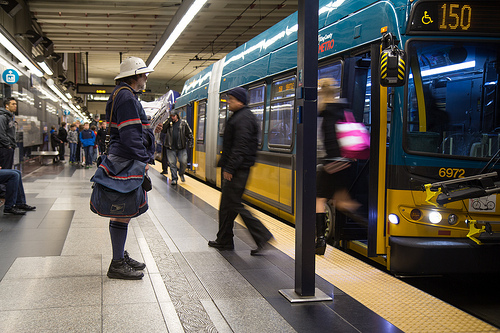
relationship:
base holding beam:
[280, 285, 332, 305] [294, 0, 317, 296]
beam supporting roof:
[289, 0, 320, 303] [204, 50, 286, 75]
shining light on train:
[428, 210, 442, 223] [166, 0, 498, 303]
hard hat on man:
[113, 55, 153, 79] [72, 81, 186, 202]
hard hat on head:
[113, 55, 153, 79] [95, 40, 167, 94]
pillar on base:
[297, 0, 315, 300] [276, 287, 331, 303]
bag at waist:
[85, 152, 156, 221] [94, 145, 162, 181]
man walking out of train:
[207, 88, 281, 256] [166, 0, 498, 303]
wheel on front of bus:
[311, 194, 343, 253] [159, 16, 491, 273]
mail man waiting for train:
[90, 55, 155, 280] [166, 0, 498, 303]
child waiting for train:
[67, 123, 78, 166] [166, 0, 498, 303]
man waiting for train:
[1, 98, 20, 170] [166, 0, 498, 303]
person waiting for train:
[0, 167, 35, 217] [166, 0, 498, 303]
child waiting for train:
[78, 122, 95, 166] [166, 0, 498, 303]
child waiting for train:
[67, 123, 78, 166] [172, 23, 498, 287]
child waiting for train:
[78, 122, 95, 166] [172, 23, 498, 287]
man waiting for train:
[1, 97, 41, 219] [125, 22, 497, 289]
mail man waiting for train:
[88, 55, 155, 280] [154, 0, 499, 279]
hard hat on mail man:
[113, 55, 153, 79] [90, 55, 155, 280]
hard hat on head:
[113, 55, 153, 79] [116, 57, 153, 92]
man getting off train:
[207, 80, 282, 262] [151, 10, 482, 272]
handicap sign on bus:
[421, 11, 434, 25] [174, 0, 496, 277]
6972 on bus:
[438, 167, 465, 178] [174, 0, 496, 277]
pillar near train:
[292, 0, 319, 300] [167, 14, 487, 259]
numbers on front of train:
[430, 163, 470, 183] [166, 0, 498, 303]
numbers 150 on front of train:
[437, 2, 469, 30] [154, 0, 499, 279]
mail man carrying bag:
[90, 55, 155, 280] [89, 153, 154, 220]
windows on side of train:
[215, 79, 326, 182] [151, 10, 482, 272]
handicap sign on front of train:
[417, 7, 435, 27] [154, 0, 499, 279]